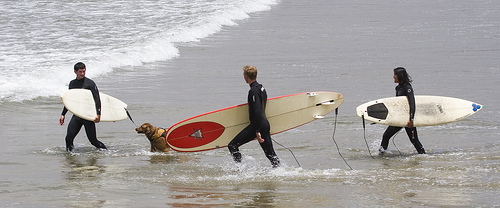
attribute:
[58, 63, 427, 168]
people — walking, together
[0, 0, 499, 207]
water — blue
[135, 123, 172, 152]
dog — golden retriever, alone, brow, walkig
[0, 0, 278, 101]
wave — breaking, crashing ashore, white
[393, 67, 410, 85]
hair — long, black, log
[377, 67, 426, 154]
woman — walking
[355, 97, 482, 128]
surboard — white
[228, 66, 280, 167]
man — blonde haired, blonde, walking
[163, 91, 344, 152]
surfboard — red white, black, large, white, red, tan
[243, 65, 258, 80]
hair — blonde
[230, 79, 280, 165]
wetsuit — black, black colored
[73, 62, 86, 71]
hair — dark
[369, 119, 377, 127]
fin — black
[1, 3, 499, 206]
beach — sandy